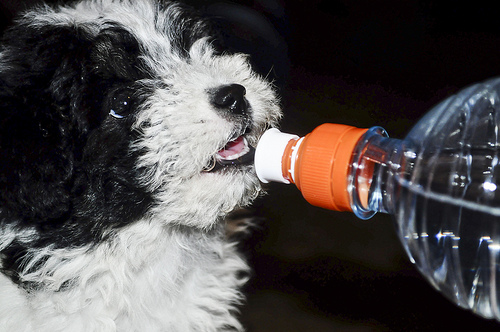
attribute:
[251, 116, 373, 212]
top — orange, screw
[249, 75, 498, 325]
bottle — water